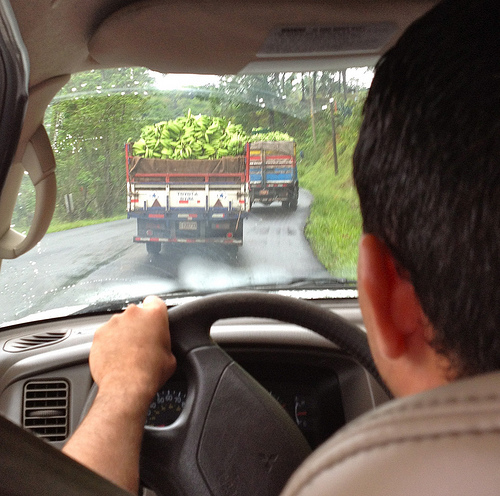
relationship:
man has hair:
[60, 1, 499, 494] [351, 1, 498, 383]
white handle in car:
[5, 156, 64, 245] [13, 136, 453, 479]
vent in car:
[21, 374, 72, 443] [3, 17, 484, 493]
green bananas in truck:
[130, 107, 249, 164] [122, 137, 252, 264]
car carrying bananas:
[126, 141, 251, 258] [130, 108, 249, 161]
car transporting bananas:
[126, 141, 250, 255] [125, 113, 245, 161]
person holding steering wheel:
[62, 9, 498, 489] [83, 288, 396, 494]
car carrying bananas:
[126, 141, 250, 255] [133, 111, 243, 155]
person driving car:
[62, 9, 498, 489] [3, 17, 484, 493]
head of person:
[353, 0, 498, 398] [277, 2, 497, 494]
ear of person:
[348, 229, 415, 364] [62, 9, 498, 489]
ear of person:
[354, 229, 418, 365] [62, 9, 498, 489]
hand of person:
[85, 295, 175, 392] [62, 9, 498, 489]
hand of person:
[88, 295, 175, 387] [62, 9, 498, 489]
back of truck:
[123, 94, 338, 190] [103, 111, 268, 246]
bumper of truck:
[124, 229, 246, 249] [113, 132, 253, 267]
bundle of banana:
[169, 121, 180, 137] [237, 123, 239, 134]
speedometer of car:
[132, 380, 187, 425] [0, 0, 432, 479]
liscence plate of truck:
[158, 199, 205, 239] [126, 113, 322, 262]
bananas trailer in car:
[125, 110, 249, 257] [126, 141, 250, 255]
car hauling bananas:
[126, 141, 250, 255] [130, 108, 249, 161]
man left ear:
[60, 1, 499, 494] [359, 233, 417, 360]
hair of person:
[351, 1, 498, 383] [62, 9, 498, 489]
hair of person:
[351, 36, 498, 357] [332, 17, 484, 339]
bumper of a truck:
[132, 233, 244, 246] [123, 136, 249, 255]